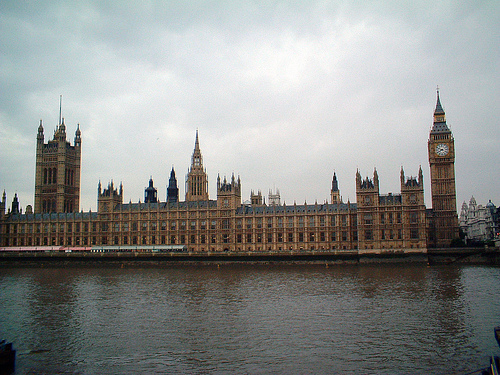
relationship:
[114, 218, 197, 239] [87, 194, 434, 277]
windows on buliding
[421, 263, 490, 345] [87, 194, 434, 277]
reflection of buliding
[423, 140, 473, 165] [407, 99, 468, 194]
clock on tower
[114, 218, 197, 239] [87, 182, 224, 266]
windows on side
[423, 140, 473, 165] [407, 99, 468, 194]
clock in tower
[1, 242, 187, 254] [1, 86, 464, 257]
canopies in front of building